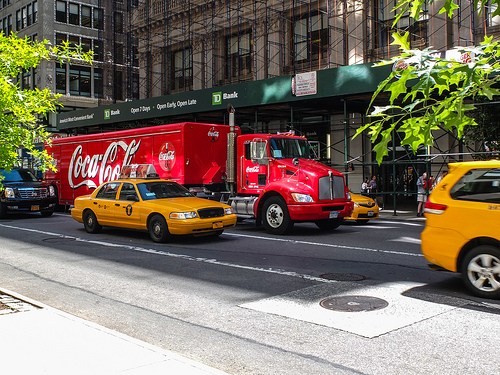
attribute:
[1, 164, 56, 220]
suv — black 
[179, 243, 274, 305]
pizza — Green 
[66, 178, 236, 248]
taxi cab — yellow 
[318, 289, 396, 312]
manhole — black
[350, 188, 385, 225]
taxi — yellow 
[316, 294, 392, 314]
man hole — metal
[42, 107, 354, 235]
truck — red, large, semi, coca cola truck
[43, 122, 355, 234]
truck — red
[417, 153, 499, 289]
car — yellow 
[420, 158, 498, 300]
suv — yellow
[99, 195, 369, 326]
line — white, faded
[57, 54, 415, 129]
sign — long, green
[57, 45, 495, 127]
sign — green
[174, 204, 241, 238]
plate — yellow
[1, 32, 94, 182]
leaves — very green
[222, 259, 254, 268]
lines — White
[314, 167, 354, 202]
grill — large